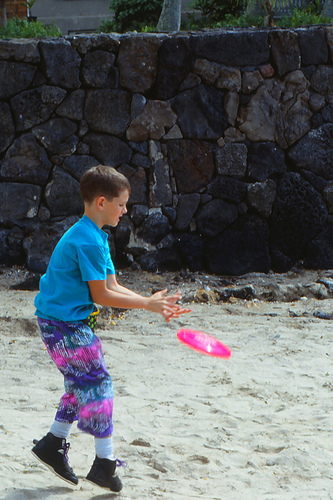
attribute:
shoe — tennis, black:
[86, 455, 122, 491]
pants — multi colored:
[41, 324, 105, 434]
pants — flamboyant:
[34, 314, 115, 437]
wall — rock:
[184, 23, 301, 242]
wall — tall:
[1, 43, 331, 162]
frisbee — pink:
[177, 328, 231, 359]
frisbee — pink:
[174, 320, 234, 368]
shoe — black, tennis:
[36, 430, 83, 487]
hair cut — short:
[59, 155, 135, 205]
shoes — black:
[31, 430, 129, 494]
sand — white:
[0, 289, 332, 499]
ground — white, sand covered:
[0, 270, 332, 498]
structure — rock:
[134, 53, 296, 248]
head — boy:
[71, 165, 133, 228]